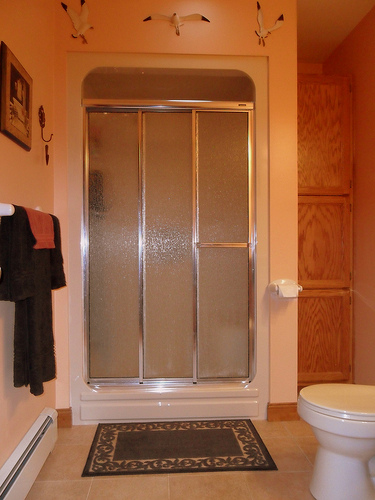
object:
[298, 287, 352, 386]
wooden cabinet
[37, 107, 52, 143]
hook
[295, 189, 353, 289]
cabinet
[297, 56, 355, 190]
cabinet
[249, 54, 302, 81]
ground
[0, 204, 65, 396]
black towel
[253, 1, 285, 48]
bird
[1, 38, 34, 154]
picture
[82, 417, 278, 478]
bath mat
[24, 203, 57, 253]
towel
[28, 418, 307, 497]
floor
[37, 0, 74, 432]
corner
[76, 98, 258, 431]
cabinet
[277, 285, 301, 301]
tissue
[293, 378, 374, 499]
toilet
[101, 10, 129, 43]
wall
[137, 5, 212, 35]
decoration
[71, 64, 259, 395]
shower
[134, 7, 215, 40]
bird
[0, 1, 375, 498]
bathroom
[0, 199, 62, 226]
rack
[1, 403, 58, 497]
wall heater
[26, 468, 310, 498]
tile